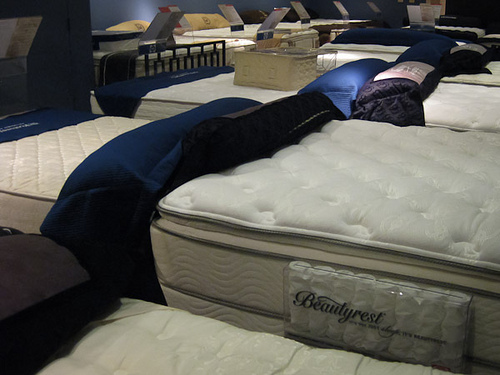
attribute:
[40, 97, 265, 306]
pillow — blue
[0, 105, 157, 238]
mattress — white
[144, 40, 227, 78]
headboard — black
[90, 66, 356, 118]
mattress — white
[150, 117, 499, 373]
mattress — white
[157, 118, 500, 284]
pillow top — white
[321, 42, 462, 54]
mattress — white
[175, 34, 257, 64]
mattress — white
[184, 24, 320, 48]
mattress — white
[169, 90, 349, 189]
pillow — gray, black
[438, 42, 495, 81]
pillow — black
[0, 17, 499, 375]
store — bed store, in mattress store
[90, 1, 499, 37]
wall — blue, dark blue, pale blue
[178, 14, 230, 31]
pillow — mustard yellow, long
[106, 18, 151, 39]
pillow — mustard yellow, long